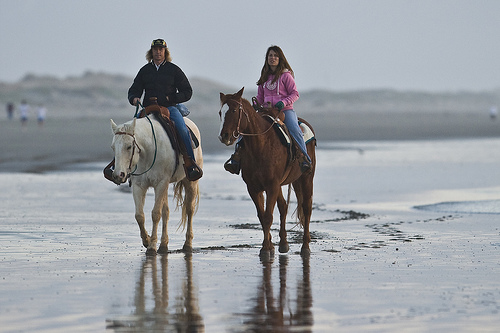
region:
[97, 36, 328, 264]
two people riding horses on a beach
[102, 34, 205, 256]
man riding a white horse on a beach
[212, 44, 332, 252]
woman riding a brown horse on a beach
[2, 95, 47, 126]
3 people in the distance on a beach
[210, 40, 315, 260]
girl with pink jacket riding horse on beach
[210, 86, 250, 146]
brown horse with a white forehead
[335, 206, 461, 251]
hoofprints on a wet beach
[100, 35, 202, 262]
man wearing a ballcap while riding a horse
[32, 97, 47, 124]
person with white shirt on in the distance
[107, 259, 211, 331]
reflection of horse on the sand on the beach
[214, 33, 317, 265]
The woman is riding a horse.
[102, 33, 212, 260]
The man is riding a horse.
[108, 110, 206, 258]
The horse is white.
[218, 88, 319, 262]
The horse is brown and white.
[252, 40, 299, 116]
The woman has hair.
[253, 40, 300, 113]
The woman's hair is long.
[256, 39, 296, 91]
The woman's hair is brown.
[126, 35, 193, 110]
The man is wearing a cap.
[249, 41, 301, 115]
The woman is wearing a pink jacket.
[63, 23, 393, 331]
The horse are walking through water.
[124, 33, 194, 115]
The man has slightly long hair.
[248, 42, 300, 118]
The jacket has sleeves.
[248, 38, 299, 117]
The jacket sleeves are long.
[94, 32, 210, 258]
The man is riding the horse.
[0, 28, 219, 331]
The hosre is walking through water.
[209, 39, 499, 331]
The horse is walking through water.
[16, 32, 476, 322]
Two people riding horses.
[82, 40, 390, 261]
The horse riders are on the beach.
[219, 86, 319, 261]
The horse is primarily brown.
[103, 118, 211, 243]
The horse is mostly white.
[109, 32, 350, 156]
The two people look towards the camera.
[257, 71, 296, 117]
The woman wears a pink top.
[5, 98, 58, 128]
People in the background.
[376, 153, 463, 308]
The water is smooth.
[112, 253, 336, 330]
Reflection of thehorses.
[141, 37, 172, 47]
The man wears a hat.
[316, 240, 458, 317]
the sand is wet and grey.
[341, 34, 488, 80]
the sky is light blue.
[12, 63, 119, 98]
a big brown mountain.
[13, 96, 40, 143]
a woman is wearing a blue shirt.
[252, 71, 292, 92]
a woman is wearing a pink and white jacket.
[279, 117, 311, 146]
a woman is wearing blue pants.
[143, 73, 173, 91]
a man is wearing a black jacket.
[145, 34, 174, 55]
a man is wearing a black and yellow cap.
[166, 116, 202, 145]
a man is wearing blue jeans.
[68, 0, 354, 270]
a man and woman are riding horses on the beach.